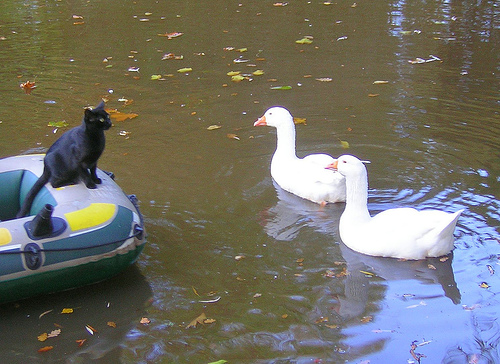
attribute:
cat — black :
[41, 90, 119, 205]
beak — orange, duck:
[246, 110, 264, 129]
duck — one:
[248, 90, 346, 214]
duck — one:
[322, 147, 468, 265]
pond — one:
[319, 47, 460, 149]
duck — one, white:
[325, 148, 460, 262]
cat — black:
[38, 88, 111, 202]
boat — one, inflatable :
[1, 148, 151, 298]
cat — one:
[40, 96, 111, 194]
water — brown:
[176, 163, 276, 275]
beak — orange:
[238, 104, 288, 142]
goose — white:
[242, 96, 370, 228]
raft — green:
[0, 129, 153, 311]